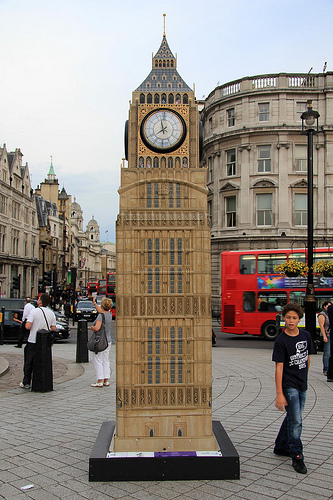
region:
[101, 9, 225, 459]
gold and grey clock tower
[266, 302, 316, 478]
young man wearing black shirt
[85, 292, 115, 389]
woman wearing gray shirt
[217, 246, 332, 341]
red double decker bus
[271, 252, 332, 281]
yellow flowers hanging from light fixture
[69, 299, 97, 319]
black car on the road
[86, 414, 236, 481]
black base of the clock tower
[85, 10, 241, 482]
A CLOCK TOWER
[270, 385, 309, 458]
A PAIR OF BLUE JEANS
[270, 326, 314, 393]
A BLACK TEE SHIRT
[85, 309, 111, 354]
A GRAY HANDBAG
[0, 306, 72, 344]
A BLACK CAR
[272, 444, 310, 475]
A PAIR OF BLACK SHOES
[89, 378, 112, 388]
A PAIR OF WHITE SHOES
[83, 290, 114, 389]
A WOMAN WEARING WHITE PANTS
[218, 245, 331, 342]
A DOUBLE DECKER BUS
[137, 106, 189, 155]
A CLOCK SHOWING 11:40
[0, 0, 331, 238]
light in daytime sky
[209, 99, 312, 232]
windows on curved building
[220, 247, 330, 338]
side of red double decker bus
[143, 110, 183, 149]
clock with white face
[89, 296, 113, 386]
woman with hand up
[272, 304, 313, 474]
walking boy in blue jeans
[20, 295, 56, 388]
man in white shirt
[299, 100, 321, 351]
light on black post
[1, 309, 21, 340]
person sitting in car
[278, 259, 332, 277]
flowers in hanging baskets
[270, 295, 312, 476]
This is a person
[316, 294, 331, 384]
This is a person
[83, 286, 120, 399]
This is a person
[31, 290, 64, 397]
This is a person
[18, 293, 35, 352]
This is a person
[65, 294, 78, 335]
This is a person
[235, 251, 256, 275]
Window of a bus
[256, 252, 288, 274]
Window of a bus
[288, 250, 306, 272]
Window of a bus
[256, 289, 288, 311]
Window of a bus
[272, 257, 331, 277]
Two colorful flower pots hanging from a lampost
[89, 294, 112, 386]
Woman in white pants taking a picture with her smartphone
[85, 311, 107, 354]
Oversized black handbag, hobo style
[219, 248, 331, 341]
Double decker bus with advertisements on the side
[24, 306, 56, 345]
Man's white t shirt with a strap across the middle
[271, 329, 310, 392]
Older boy in a black t shirt with white writing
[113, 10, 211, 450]
Statue of a small Big Ben set in the middle of the pavement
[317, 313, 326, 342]
Bare arm of a person wearing a vest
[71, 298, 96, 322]
Dark colored car with headlights illuminated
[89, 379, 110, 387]
White comfortable women's walking shoes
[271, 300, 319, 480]
boy standing by a clock tower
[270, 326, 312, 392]
boy's black and white tee shirt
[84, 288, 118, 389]
woman raising her right hand